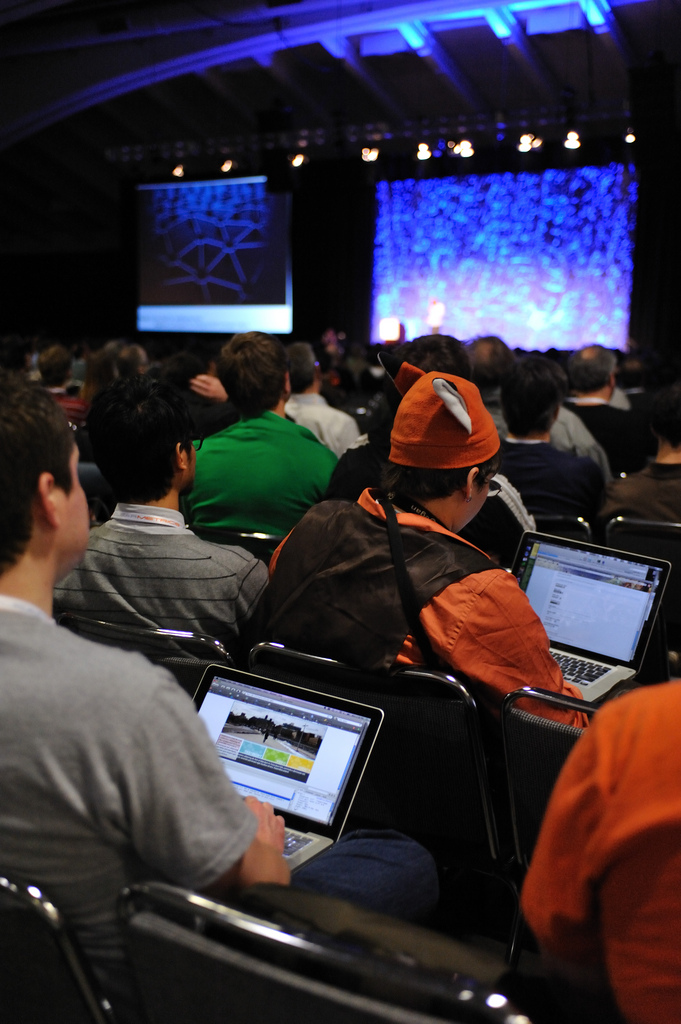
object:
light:
[361, 147, 378, 163]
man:
[0, 380, 445, 971]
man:
[264, 367, 589, 731]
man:
[181, 329, 340, 539]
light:
[564, 131, 581, 150]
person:
[246, 370, 588, 726]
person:
[517, 681, 681, 1024]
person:
[51, 372, 271, 660]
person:
[596, 383, 681, 548]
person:
[491, 356, 604, 536]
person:
[180, 331, 340, 545]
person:
[32, 340, 79, 398]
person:
[284, 340, 360, 460]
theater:
[0, 6, 681, 1024]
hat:
[388, 369, 502, 471]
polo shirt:
[180, 405, 337, 564]